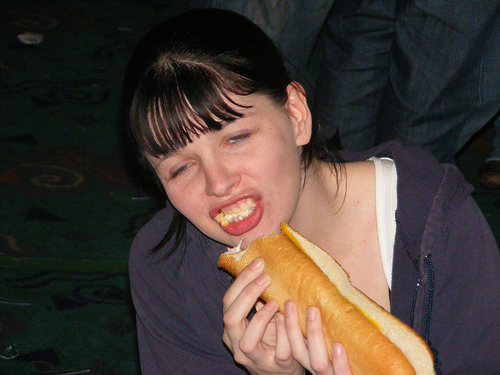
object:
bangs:
[120, 63, 259, 159]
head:
[121, 12, 312, 253]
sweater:
[126, 140, 500, 375]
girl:
[126, 20, 500, 375]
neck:
[290, 153, 336, 245]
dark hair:
[115, 9, 297, 158]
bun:
[215, 221, 435, 375]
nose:
[203, 157, 239, 198]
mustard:
[342, 295, 384, 333]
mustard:
[279, 222, 304, 252]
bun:
[214, 211, 232, 225]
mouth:
[208, 190, 262, 240]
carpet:
[0, 2, 136, 375]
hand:
[285, 298, 352, 375]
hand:
[221, 257, 302, 375]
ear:
[283, 81, 311, 146]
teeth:
[213, 196, 260, 226]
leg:
[308, 1, 410, 168]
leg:
[384, 2, 496, 176]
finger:
[305, 306, 330, 375]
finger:
[332, 342, 352, 375]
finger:
[284, 301, 306, 362]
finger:
[275, 314, 292, 359]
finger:
[224, 275, 273, 322]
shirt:
[367, 155, 403, 287]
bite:
[214, 223, 299, 259]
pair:
[323, 6, 500, 162]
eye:
[218, 127, 255, 148]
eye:
[166, 156, 193, 178]